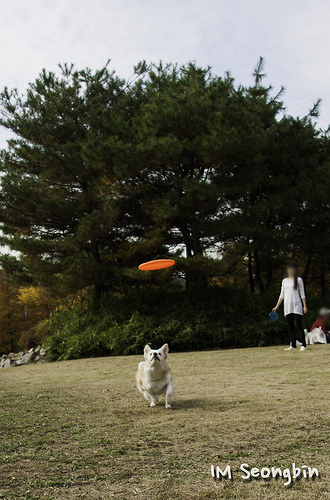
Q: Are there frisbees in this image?
A: Yes, there is a frisbee.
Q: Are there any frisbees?
A: Yes, there is a frisbee.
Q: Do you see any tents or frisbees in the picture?
A: Yes, there is a frisbee.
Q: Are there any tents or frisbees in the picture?
A: Yes, there is a frisbee.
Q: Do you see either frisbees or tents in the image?
A: Yes, there is a frisbee.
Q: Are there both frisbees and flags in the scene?
A: No, there is a frisbee but no flags.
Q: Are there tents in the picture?
A: No, there are no tents.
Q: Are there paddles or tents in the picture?
A: No, there are no tents or paddles.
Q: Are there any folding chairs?
A: No, there are no folding chairs.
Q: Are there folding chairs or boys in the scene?
A: No, there are no folding chairs or boys.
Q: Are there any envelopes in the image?
A: No, there are no envelopes.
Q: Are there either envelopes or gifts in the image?
A: No, there are no envelopes or gifts.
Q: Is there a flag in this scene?
A: No, there are no flags.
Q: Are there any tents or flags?
A: No, there are no flags or tents.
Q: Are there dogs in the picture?
A: Yes, there is a dog.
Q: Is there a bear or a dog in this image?
A: Yes, there is a dog.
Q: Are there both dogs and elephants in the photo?
A: No, there is a dog but no elephants.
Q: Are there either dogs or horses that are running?
A: Yes, the dog is running.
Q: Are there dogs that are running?
A: Yes, there is a dog that is running.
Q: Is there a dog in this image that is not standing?
A: Yes, there is a dog that is running.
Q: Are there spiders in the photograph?
A: No, there are no spiders.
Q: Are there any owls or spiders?
A: No, there are no spiders or owls.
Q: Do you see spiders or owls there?
A: No, there are no spiders or owls.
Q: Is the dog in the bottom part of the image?
A: Yes, the dog is in the bottom of the image.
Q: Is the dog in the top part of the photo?
A: No, the dog is in the bottom of the image.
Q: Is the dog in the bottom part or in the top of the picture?
A: The dog is in the bottom of the image.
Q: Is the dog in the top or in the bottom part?
A: The dog is in the bottom of the image.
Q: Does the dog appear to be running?
A: Yes, the dog is running.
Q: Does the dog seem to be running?
A: Yes, the dog is running.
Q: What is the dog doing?
A: The dog is running.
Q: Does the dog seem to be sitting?
A: No, the dog is running.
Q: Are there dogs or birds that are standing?
A: No, there is a dog but it is running.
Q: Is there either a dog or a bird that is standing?
A: No, there is a dog but it is running.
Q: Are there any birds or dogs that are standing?
A: No, there is a dog but it is running.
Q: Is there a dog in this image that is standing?
A: No, there is a dog but it is running.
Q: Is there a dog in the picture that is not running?
A: No, there is a dog but it is running.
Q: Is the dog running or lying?
A: The dog is running.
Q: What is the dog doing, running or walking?
A: The dog is running.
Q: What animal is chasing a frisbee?
A: The dog is chasing a frisbee.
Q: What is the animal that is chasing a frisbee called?
A: The animal is a dog.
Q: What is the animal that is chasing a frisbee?
A: The animal is a dog.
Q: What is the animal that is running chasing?
A: The dog is chasing a frisbee.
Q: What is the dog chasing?
A: The dog is chasing a frisbee.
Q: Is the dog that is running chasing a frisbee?
A: Yes, the dog is chasing a frisbee.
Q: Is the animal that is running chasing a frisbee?
A: Yes, the dog is chasing a frisbee.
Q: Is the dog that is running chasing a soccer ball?
A: No, the dog is chasing a frisbee.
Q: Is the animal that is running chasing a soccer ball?
A: No, the dog is chasing a frisbee.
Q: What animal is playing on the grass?
A: The dog is playing on the grass.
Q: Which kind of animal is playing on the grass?
A: The animal is a dog.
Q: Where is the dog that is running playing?
A: The dog is playing on the grass.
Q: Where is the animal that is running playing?
A: The dog is playing on the grass.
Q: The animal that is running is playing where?
A: The dog is playing on the grass.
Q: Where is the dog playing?
A: The dog is playing on the grass.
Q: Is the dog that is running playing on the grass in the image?
A: Yes, the dog is playing on the grass.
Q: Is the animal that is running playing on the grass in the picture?
A: Yes, the dog is playing on the grass.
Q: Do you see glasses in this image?
A: No, there are no glasses.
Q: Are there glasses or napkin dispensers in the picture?
A: No, there are no glasses or napkin dispensers.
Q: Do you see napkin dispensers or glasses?
A: No, there are no glasses or napkin dispensers.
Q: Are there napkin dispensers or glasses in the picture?
A: No, there are no glasses or napkin dispensers.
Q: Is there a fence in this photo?
A: No, there are no fences.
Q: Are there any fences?
A: No, there are no fences.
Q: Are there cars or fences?
A: No, there are no fences or cars.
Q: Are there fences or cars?
A: No, there are no fences or cars.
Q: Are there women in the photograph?
A: Yes, there is a woman.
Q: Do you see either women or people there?
A: Yes, there is a woman.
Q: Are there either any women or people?
A: Yes, there is a woman.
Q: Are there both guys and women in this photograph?
A: No, there is a woman but no guys.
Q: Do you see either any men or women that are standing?
A: Yes, the woman is standing.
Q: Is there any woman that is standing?
A: Yes, there is a woman that is standing.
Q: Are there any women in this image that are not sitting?
A: Yes, there is a woman that is standing.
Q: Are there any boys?
A: No, there are no boys.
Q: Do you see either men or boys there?
A: No, there are no boys or men.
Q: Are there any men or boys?
A: No, there are no boys or men.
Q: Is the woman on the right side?
A: Yes, the woman is on the right of the image.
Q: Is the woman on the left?
A: No, the woman is on the right of the image.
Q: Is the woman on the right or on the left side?
A: The woman is on the right of the image.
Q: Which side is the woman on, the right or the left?
A: The woman is on the right of the image.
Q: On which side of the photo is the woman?
A: The woman is on the right of the image.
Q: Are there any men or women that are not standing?
A: No, there is a woman but she is standing.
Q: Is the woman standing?
A: Yes, the woman is standing.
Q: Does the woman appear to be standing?
A: Yes, the woman is standing.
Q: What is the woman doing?
A: The woman is standing.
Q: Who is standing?
A: The woman is standing.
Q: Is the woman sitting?
A: No, the woman is standing.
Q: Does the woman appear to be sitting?
A: No, the woman is standing.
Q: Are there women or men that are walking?
A: No, there is a woman but she is standing.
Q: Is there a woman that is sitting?
A: No, there is a woman but she is standing.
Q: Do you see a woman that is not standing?
A: No, there is a woman but she is standing.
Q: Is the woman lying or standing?
A: The woman is standing.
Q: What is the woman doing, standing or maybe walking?
A: The woman is standing.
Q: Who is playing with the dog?
A: The woman is playing with the dog.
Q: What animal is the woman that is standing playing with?
A: The woman is playing with the dog.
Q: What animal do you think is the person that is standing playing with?
A: The woman is playing with the dog.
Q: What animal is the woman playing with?
A: The woman is playing with the dog.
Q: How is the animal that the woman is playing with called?
A: The animal is a dog.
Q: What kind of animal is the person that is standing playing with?
A: The woman is playing with the dog.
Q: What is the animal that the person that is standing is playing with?
A: The animal is a dog.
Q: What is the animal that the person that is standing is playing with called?
A: The animal is a dog.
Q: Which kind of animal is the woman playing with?
A: The woman is playing with the dog.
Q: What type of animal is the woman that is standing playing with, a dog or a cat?
A: The woman is playing with a dog.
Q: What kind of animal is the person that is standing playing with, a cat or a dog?
A: The woman is playing with a dog.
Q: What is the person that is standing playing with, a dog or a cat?
A: The woman is playing with a dog.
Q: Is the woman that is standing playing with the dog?
A: Yes, the woman is playing with the dog.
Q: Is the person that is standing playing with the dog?
A: Yes, the woman is playing with the dog.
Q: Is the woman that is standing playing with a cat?
A: No, the woman is playing with the dog.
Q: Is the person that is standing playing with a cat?
A: No, the woman is playing with the dog.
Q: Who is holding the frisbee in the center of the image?
A: The woman is holding the frisbee.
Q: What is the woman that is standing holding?
A: The woman is holding the frisbee.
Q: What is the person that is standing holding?
A: The woman is holding the frisbee.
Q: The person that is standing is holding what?
A: The woman is holding the frisbee.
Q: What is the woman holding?
A: The woman is holding the frisbee.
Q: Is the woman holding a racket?
A: No, the woman is holding the frisbee.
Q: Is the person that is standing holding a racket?
A: No, the woman is holding the frisbee.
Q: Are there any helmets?
A: No, there are no helmets.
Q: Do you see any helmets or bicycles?
A: No, there are no helmets or bicycles.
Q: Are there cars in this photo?
A: No, there are no cars.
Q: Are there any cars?
A: No, there are no cars.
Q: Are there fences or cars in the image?
A: No, there are no cars or fences.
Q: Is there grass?
A: Yes, there is grass.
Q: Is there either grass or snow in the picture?
A: Yes, there is grass.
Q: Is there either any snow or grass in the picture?
A: Yes, there is grass.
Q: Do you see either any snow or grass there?
A: Yes, there is grass.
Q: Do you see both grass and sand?
A: No, there is grass but no sand.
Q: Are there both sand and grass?
A: No, there is grass but no sand.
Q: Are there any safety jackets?
A: No, there are no safety jackets.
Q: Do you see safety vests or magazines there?
A: No, there are no safety vests or magazines.